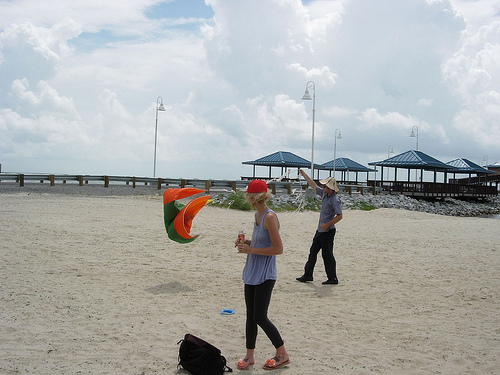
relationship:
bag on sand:
[177, 332, 233, 374] [1, 194, 497, 375]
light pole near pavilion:
[302, 79, 316, 202] [367, 148, 461, 205]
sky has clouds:
[4, 2, 493, 174] [2, 0, 500, 170]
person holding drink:
[233, 177, 294, 370] [238, 232, 246, 246]